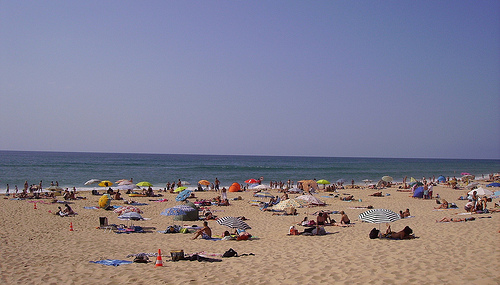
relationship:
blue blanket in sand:
[91, 251, 131, 271] [0, 188, 495, 281]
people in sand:
[189, 221, 212, 240] [0, 173, 497, 283]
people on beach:
[189, 217, 253, 242] [2, 169, 498, 284]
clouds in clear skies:
[2, 78, 329, 153] [0, 1, 500, 159]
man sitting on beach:
[96, 190, 113, 212] [2, 169, 498, 284]